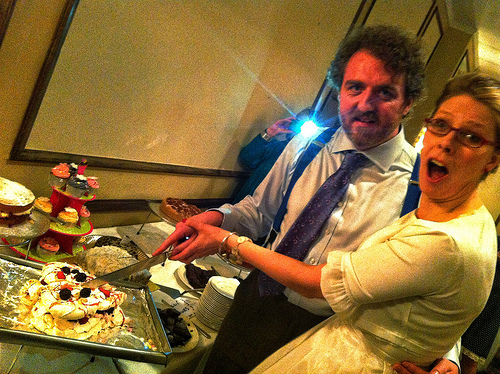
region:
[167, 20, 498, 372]
A man and a woman stand together.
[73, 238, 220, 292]
Knife being held by both man and woman.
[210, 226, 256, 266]
Two bracelets being worn by woman.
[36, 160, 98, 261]
Colorful three tier display with cupcakes on it.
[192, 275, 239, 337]
Stack of white plates on table.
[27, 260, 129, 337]
Heart shaped dessert on foiled pan.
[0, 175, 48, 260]
Two layer cake with cream in middle on tray stand.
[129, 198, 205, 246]
Chocolate centered dessert in crust on metal stand.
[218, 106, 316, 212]
Person in blue shirt with camera.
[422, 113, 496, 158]
Eyeglasses be worn by woman in white.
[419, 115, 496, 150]
woman wearing red glasses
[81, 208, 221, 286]
a man and a woman holding a knife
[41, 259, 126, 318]
a cake shaped like a heart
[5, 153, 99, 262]
a colorful display of cupcakes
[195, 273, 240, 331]
a stack of white plates on a table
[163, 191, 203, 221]
a chocolate pie on a metal tray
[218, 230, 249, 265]
a woman wearing bracelets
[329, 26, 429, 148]
man with brown curly hair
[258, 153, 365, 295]
man wearing a purple tie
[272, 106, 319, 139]
person taking a picture with a flash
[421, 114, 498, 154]
glasses on the woman's face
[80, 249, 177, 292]
knife in the couple's hands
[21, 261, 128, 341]
cake being cut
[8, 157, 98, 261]
cup cake tier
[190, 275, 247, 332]
pile of white plates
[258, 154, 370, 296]
dark blue tie on the man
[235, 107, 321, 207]
person taking a picture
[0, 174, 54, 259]
cake on a platter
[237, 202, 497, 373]
the woman is wearing a white dress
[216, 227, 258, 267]
bracelets on the woman's wrist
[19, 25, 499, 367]
a couple cutting a heart shaped cake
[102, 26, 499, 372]
a hugging couple holding a long cake knife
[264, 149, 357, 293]
a blue silk tie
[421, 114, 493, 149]
a pair of red framed galsses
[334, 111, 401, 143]
a brown beard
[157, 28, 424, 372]
a guy wearing blue suspenders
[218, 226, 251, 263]
two shiny bracelets on wrist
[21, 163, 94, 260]
a red dessert platter display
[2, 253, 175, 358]
a rectangle metal cooking sheet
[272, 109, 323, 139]
a camera with flash on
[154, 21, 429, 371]
man in shirt and tie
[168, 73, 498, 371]
woman in long sleeved white dress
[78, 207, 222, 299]
two hands and a shiny knife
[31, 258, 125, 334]
heart shaped cake with white frosting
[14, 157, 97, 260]
red cupcake tower with assorted cupcakes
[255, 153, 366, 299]
blue patterned neck tie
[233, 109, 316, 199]
person taking photo with flash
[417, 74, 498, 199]
surprised woman head wearing glasses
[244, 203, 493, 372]
white long sleeved dress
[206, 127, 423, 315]
long sleeved shirt with tie and suspenders